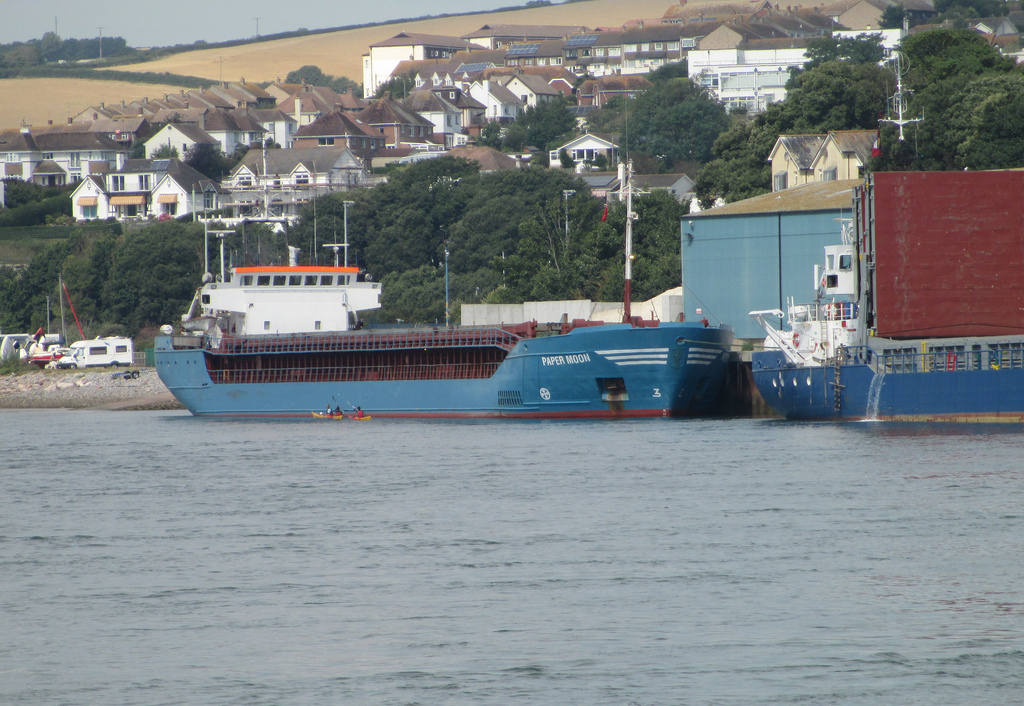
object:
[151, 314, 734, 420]
boat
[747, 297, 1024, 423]
boat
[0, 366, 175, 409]
rocks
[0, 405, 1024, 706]
water